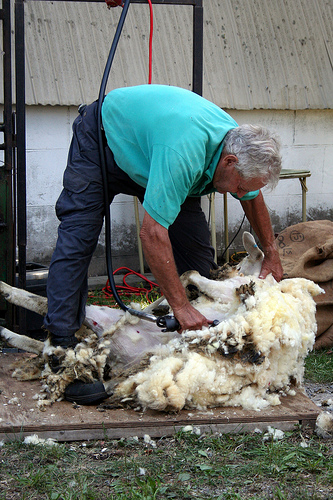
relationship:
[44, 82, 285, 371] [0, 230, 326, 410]
man sheering a sheep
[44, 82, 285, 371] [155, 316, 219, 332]
man holding clippers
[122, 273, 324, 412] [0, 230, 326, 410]
wool from sheep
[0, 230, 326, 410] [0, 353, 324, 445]
sheep laying on wood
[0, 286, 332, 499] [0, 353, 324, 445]
grass under wood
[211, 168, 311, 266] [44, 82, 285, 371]
table behind man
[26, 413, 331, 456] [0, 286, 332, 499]
wool on grass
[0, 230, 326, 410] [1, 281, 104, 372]
sheep has legs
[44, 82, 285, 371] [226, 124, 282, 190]
man has hair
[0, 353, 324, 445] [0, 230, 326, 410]
wood under sheep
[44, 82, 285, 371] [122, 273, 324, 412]
man cuts sheep wool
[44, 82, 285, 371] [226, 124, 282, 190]
man has gray hair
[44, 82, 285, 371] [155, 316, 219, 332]
man using clipper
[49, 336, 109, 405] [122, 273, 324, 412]
boot near wool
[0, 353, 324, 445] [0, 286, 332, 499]
wood on top of grass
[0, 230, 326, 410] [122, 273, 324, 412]
sheep body has no wool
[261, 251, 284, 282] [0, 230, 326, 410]
hand holding sheep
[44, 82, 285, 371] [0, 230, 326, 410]
man shaves sheep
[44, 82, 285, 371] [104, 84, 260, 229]
man wearing green shirt